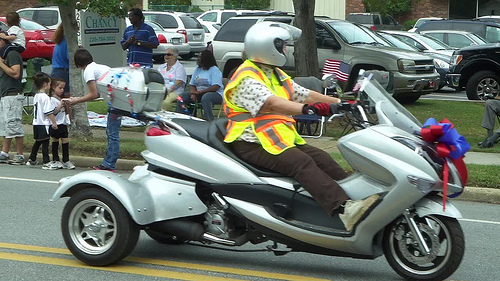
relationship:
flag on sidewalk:
[320, 58, 353, 83] [95, 128, 144, 144]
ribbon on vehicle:
[421, 115, 468, 212] [48, 71, 464, 280]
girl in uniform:
[48, 74, 75, 172] [48, 94, 70, 161]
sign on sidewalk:
[79, 9, 129, 69] [95, 128, 144, 144]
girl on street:
[48, 74, 75, 172] [1, 156, 497, 280]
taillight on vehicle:
[145, 121, 171, 139] [48, 71, 464, 280]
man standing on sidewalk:
[117, 8, 159, 68] [95, 128, 144, 144]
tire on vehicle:
[61, 186, 142, 269] [48, 71, 464, 280]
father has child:
[0, 25, 27, 165] [0, 9, 26, 74]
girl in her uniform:
[48, 74, 75, 172] [48, 94, 70, 161]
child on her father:
[0, 9, 26, 74] [0, 25, 27, 165]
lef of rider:
[258, 144, 346, 214] [225, 20, 383, 232]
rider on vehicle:
[225, 20, 383, 232] [48, 71, 464, 280]